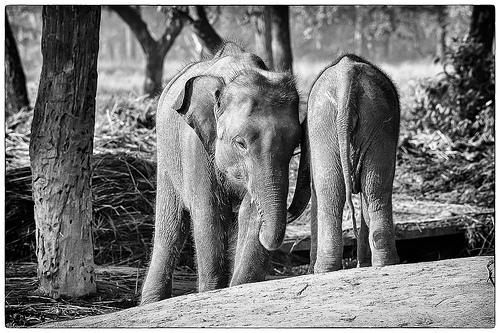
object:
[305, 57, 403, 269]
elephant's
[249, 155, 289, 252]
trunk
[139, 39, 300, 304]
baby elephant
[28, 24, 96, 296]
bark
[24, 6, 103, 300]
trunk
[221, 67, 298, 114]
baby hair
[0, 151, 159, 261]
straw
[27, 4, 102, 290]
tree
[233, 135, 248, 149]
eye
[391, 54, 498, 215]
foliage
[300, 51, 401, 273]
baby elephants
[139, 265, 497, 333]
hill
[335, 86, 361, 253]
elephant tail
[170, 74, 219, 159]
ear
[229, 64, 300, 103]
hair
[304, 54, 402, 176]
but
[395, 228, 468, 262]
dark cave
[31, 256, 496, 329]
ground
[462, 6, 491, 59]
tree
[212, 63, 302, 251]
elephant head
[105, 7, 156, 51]
branch